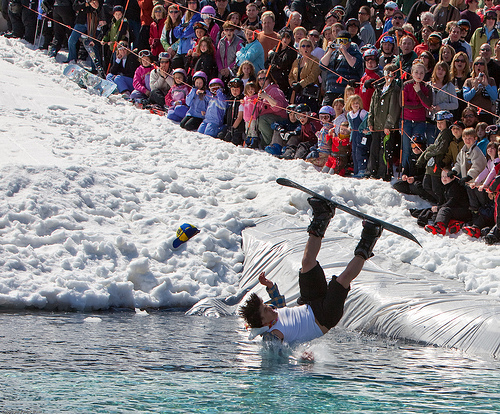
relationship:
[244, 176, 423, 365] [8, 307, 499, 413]
snowboarder in water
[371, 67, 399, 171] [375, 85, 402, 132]
girl in jacket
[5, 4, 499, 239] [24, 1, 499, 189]
audience behind rope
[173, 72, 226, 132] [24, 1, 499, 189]
child gripping rope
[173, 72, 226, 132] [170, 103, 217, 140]
child on their knees